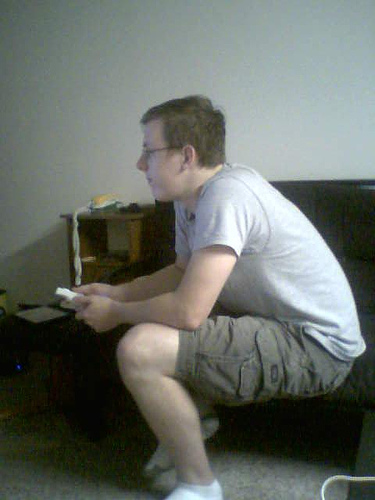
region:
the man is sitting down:
[57, 92, 369, 498]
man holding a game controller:
[53, 92, 369, 498]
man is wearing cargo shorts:
[170, 302, 350, 403]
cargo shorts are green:
[172, 317, 355, 408]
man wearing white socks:
[134, 409, 233, 499]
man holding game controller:
[50, 278, 83, 310]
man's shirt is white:
[171, 159, 368, 366]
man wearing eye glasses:
[136, 137, 186, 153]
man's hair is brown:
[138, 92, 228, 171]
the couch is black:
[77, 178, 372, 498]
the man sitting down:
[54, 95, 365, 499]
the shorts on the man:
[173, 314, 354, 405]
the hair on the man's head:
[138, 94, 225, 169]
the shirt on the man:
[173, 159, 365, 360]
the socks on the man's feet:
[143, 412, 222, 498]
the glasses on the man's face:
[139, 144, 184, 157]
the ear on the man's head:
[180, 143, 193, 170]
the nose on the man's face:
[135, 150, 147, 170]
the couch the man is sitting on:
[93, 179, 373, 443]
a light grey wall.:
[28, 23, 96, 166]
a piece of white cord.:
[319, 474, 374, 499]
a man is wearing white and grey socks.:
[145, 447, 169, 479]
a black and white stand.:
[10, 304, 71, 402]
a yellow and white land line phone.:
[70, 188, 117, 286]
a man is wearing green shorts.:
[236, 337, 293, 377]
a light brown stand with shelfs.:
[57, 206, 152, 285]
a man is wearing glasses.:
[137, 140, 184, 160]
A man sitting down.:
[71, 91, 368, 498]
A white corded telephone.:
[70, 193, 122, 285]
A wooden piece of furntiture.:
[60, 202, 157, 287]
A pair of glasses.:
[141, 144, 176, 157]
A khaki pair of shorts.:
[174, 314, 352, 407]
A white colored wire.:
[320, 472, 373, 498]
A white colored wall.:
[1, 0, 374, 304]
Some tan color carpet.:
[205, 444, 351, 498]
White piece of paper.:
[15, 304, 67, 325]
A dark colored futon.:
[266, 179, 374, 405]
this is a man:
[6, 54, 370, 487]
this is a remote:
[34, 265, 119, 338]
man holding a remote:
[64, 82, 363, 498]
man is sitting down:
[100, 96, 370, 487]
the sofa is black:
[120, 141, 368, 458]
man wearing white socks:
[107, 395, 244, 498]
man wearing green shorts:
[141, 296, 336, 409]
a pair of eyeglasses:
[135, 139, 178, 167]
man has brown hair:
[132, 94, 243, 189]